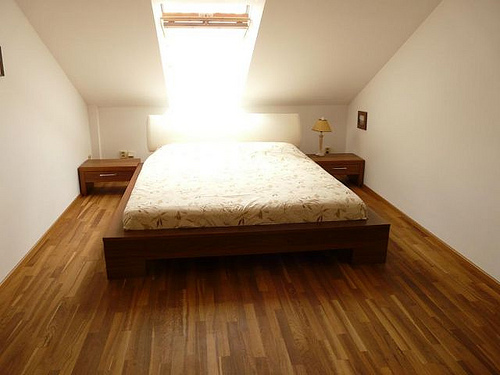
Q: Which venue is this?
A: This is a bedroom.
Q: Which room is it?
A: It is a bedroom.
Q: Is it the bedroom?
A: Yes, it is the bedroom.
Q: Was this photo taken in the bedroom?
A: Yes, it was taken in the bedroom.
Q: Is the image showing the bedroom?
A: Yes, it is showing the bedroom.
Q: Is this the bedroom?
A: Yes, it is the bedroom.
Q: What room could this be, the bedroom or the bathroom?
A: It is the bedroom.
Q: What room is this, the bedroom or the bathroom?
A: It is the bedroom.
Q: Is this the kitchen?
A: No, it is the bedroom.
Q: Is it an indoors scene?
A: Yes, it is indoors.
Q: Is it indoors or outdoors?
A: It is indoors.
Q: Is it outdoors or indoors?
A: It is indoors.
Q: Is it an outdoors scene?
A: No, it is indoors.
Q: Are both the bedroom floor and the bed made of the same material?
A: Yes, both the floor and the bed are made of wood.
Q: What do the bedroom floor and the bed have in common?
A: The material, both the floor and the bed are wooden.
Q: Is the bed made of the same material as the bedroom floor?
A: Yes, both the bed and the floor are made of wood.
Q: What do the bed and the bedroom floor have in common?
A: The material, both the bed and the floor are wooden.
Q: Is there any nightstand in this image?
A: Yes, there is a nightstand.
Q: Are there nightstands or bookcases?
A: Yes, there is a nightstand.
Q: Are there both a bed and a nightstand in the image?
A: Yes, there are both a nightstand and a bed.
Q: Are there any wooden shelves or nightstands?
A: Yes, there is a wood nightstand.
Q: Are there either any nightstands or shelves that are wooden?
A: Yes, the nightstand is wooden.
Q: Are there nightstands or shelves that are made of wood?
A: Yes, the nightstand is made of wood.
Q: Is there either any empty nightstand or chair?
A: Yes, there is an empty nightstand.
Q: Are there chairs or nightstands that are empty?
A: Yes, the nightstand is empty.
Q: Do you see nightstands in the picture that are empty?
A: Yes, there is an empty nightstand.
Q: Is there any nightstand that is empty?
A: Yes, there is a nightstand that is empty.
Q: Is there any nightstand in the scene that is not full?
A: Yes, there is a empty nightstand.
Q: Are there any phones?
A: No, there are no phones.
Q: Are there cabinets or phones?
A: No, there are no phones or cabinets.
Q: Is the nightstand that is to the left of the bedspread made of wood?
A: Yes, the nightstand is made of wood.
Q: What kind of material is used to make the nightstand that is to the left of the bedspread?
A: The nightstand is made of wood.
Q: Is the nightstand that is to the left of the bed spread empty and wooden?
A: Yes, the nightstand is empty and wooden.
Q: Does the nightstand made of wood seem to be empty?
A: Yes, the nightstand is empty.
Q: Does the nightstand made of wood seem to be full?
A: No, the nightstand is empty.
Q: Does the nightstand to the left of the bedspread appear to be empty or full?
A: The nightstand is empty.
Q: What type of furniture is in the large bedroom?
A: The piece of furniture is a nightstand.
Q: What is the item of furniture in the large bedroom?
A: The piece of furniture is a nightstand.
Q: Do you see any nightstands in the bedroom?
A: Yes, there is a nightstand in the bedroom.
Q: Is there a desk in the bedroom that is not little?
A: No, there is a nightstand in the bedroom.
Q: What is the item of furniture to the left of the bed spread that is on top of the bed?
A: The piece of furniture is a nightstand.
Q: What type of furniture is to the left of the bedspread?
A: The piece of furniture is a nightstand.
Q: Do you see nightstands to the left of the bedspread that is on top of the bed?
A: Yes, there is a nightstand to the left of the bedspread.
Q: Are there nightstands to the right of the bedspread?
A: No, the nightstand is to the left of the bedspread.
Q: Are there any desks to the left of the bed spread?
A: No, there is a nightstand to the left of the bed spread.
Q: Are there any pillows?
A: No, there are no pillows.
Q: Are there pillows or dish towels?
A: No, there are no pillows or dish towels.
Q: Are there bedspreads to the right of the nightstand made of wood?
A: Yes, there is a bedspread to the right of the nightstand.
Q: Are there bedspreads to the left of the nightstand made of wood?
A: No, the bedspread is to the right of the nightstand.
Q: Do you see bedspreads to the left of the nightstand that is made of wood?
A: No, the bedspread is to the right of the nightstand.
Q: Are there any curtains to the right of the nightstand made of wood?
A: No, there is a bedspread to the right of the nightstand.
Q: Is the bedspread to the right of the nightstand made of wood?
A: Yes, the bedspread is to the right of the nightstand.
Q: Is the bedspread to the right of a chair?
A: No, the bedspread is to the right of the nightstand.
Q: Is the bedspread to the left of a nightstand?
A: No, the bedspread is to the right of a nightstand.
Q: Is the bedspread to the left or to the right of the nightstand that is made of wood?
A: The bedspread is to the right of the nightstand.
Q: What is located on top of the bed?
A: The bedspread is on top of the bed.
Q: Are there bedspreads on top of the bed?
A: Yes, there is a bedspread on top of the bed.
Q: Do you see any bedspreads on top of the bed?
A: Yes, there is a bedspread on top of the bed.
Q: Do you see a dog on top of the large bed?
A: No, there is a bedspread on top of the bed.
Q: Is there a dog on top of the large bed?
A: No, there is a bedspread on top of the bed.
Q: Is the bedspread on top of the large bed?
A: Yes, the bedspread is on top of the bed.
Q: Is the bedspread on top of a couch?
A: No, the bedspread is on top of the bed.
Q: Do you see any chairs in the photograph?
A: No, there are no chairs.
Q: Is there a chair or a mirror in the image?
A: No, there are no chairs or mirrors.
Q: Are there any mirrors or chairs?
A: No, there are no chairs or mirrors.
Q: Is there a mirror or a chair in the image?
A: No, there are no chairs or mirrors.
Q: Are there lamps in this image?
A: Yes, there is a lamp.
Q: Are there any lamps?
A: Yes, there is a lamp.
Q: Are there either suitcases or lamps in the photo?
A: Yes, there is a lamp.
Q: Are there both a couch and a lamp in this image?
A: No, there is a lamp but no couches.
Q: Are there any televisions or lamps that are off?
A: Yes, the lamp is off.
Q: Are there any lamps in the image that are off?
A: Yes, there is a lamp that is off.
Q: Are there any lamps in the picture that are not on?
A: Yes, there is a lamp that is off.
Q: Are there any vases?
A: No, there are no vases.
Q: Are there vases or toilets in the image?
A: No, there are no vases or toilets.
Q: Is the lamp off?
A: Yes, the lamp is off.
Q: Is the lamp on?
A: No, the lamp is off.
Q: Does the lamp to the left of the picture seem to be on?
A: No, the lamp is off.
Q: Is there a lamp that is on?
A: No, there is a lamp but it is off.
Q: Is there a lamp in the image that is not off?
A: No, there is a lamp but it is off.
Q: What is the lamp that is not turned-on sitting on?
A: The lamp is sitting on the nightstand.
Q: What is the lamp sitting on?
A: The lamp is sitting on the nightstand.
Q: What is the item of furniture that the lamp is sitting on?
A: The piece of furniture is a nightstand.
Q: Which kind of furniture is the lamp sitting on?
A: The lamp is sitting on the nightstand.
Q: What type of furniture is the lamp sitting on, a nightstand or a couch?
A: The lamp is sitting on a nightstand.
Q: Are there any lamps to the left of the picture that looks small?
A: Yes, there is a lamp to the left of the picture.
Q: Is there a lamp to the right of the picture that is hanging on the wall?
A: No, the lamp is to the left of the picture.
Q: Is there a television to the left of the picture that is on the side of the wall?
A: No, there is a lamp to the left of the picture.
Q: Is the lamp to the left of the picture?
A: Yes, the lamp is to the left of the picture.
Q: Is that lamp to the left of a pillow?
A: No, the lamp is to the left of the picture.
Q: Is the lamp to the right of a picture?
A: No, the lamp is to the left of a picture.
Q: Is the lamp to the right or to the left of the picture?
A: The lamp is to the left of the picture.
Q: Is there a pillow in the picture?
A: No, there are no pillows.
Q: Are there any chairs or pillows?
A: No, there are no pillows or chairs.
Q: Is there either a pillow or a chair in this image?
A: No, there are no pillows or chairs.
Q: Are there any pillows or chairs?
A: No, there are no pillows or chairs.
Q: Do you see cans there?
A: No, there are no cans.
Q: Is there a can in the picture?
A: No, there are no cans.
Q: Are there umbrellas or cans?
A: No, there are no cans or umbrellas.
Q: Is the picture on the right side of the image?
A: Yes, the picture is on the right of the image.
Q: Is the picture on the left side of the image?
A: No, the picture is on the right of the image.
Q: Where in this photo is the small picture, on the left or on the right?
A: The picture is on the right of the image.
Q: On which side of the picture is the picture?
A: The picture is on the right of the image.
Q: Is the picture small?
A: Yes, the picture is small.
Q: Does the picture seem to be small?
A: Yes, the picture is small.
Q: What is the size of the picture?
A: The picture is small.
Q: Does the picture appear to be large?
A: No, the picture is small.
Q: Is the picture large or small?
A: The picture is small.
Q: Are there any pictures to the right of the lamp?
A: Yes, there is a picture to the right of the lamp.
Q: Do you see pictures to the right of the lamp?
A: Yes, there is a picture to the right of the lamp.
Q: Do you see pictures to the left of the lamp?
A: No, the picture is to the right of the lamp.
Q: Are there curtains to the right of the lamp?
A: No, there is a picture to the right of the lamp.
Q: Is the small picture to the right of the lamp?
A: Yes, the picture is to the right of the lamp.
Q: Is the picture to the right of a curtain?
A: No, the picture is to the right of the lamp.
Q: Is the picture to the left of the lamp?
A: No, the picture is to the right of the lamp.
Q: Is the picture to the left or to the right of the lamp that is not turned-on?
A: The picture is to the right of the lamp.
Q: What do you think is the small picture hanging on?
A: The picture is hanging on the wall.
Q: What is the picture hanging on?
A: The picture is hanging on the wall.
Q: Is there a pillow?
A: No, there are no pillows.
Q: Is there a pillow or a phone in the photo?
A: No, there are no pillows or phones.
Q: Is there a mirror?
A: No, there are no mirrors.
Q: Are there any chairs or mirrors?
A: No, there are no mirrors or chairs.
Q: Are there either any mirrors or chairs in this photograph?
A: No, there are no mirrors or chairs.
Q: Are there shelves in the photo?
A: No, there are no shelves.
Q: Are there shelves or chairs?
A: No, there are no shelves or chairs.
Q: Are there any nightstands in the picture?
A: Yes, there is a nightstand.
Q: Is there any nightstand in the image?
A: Yes, there is a nightstand.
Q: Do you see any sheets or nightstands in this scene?
A: Yes, there is a nightstand.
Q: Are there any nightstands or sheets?
A: Yes, there is a nightstand.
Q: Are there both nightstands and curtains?
A: No, there is a nightstand but no curtains.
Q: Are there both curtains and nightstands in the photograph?
A: No, there is a nightstand but no curtains.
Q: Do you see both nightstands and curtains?
A: No, there is a nightstand but no curtains.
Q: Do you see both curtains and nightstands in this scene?
A: No, there is a nightstand but no curtains.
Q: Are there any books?
A: No, there are no books.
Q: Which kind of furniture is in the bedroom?
A: The piece of furniture is a nightstand.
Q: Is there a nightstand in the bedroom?
A: Yes, there is a nightstand in the bedroom.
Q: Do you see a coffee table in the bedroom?
A: No, there is a nightstand in the bedroom.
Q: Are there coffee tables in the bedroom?
A: No, there is a nightstand in the bedroom.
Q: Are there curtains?
A: No, there are no curtains.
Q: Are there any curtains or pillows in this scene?
A: No, there are no curtains or pillows.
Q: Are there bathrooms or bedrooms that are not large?
A: No, there is a bedroom but it is large.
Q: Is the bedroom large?
A: Yes, the bedroom is large.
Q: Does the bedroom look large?
A: Yes, the bedroom is large.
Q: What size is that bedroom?
A: The bedroom is large.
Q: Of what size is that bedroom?
A: The bedroom is large.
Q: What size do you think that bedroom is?
A: The bedroom is large.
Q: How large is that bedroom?
A: The bedroom is large.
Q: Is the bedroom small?
A: No, the bedroom is large.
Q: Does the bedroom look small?
A: No, the bedroom is large.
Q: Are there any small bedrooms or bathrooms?
A: No, there is a bedroom but it is large.